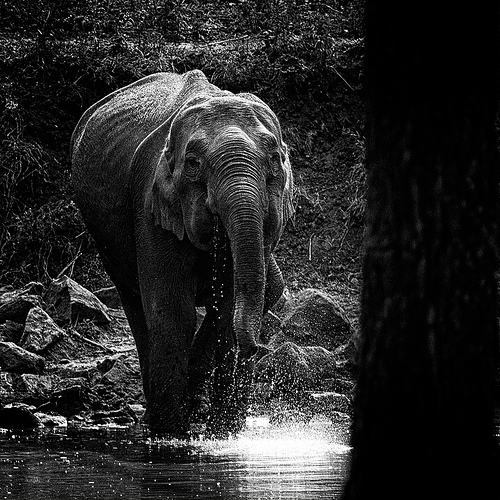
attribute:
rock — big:
[24, 277, 107, 375]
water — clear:
[9, 402, 496, 498]